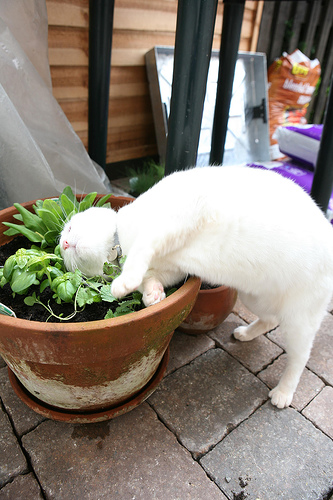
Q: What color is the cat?
A: White.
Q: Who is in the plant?
A: A cat.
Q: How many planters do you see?
A: Two.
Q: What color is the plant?
A: Green.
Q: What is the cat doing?
A: Laying in the plant.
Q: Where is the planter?
A: On the ground.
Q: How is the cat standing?
A: On back legs.